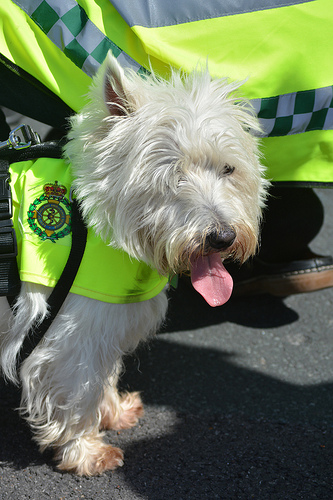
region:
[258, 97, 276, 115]
black square of fabric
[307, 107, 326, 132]
black square of fabric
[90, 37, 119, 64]
black square of fabric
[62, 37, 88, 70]
black square of fabric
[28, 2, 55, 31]
black square of fabric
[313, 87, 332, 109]
silver square of fabric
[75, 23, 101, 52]
silver square of fabric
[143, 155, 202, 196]
the eye of the dog is covered by hair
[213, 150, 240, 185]
the dog's eyes are black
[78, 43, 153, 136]
an ear is up on the dog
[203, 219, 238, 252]
the nose of the dog is black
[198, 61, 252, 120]
the dog's ear is buried in hair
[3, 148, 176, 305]
the dog is wearing a yellow coat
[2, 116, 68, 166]
the leash is attached to the dog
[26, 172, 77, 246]
an emblem is on the coat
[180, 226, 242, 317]
the doggie's tongue is pink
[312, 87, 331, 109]
grey colored fabric cloth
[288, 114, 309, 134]
grey colored fabric cloth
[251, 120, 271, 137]
grey colored fabric cloth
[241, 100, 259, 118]
grey colored fabric cloth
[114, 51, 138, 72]
grey colored fabric cloth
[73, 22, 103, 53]
grey colored fabric cloth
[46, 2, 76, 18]
grey colored fabric cloth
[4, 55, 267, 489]
This is a dog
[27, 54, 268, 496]
This is a dog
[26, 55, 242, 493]
This is a dog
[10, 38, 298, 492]
This is a dog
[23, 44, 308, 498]
This is a dog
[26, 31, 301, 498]
This is a dog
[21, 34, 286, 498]
This is a dog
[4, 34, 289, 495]
This is a dog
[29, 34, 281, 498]
This is a dog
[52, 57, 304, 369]
a shaggy dog face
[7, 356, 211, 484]
puppy feet on pavement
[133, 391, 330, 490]
shadow cast on concrete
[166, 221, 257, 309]
hot dog pants to beat the heat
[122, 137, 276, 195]
the dogs eyes are covered by fur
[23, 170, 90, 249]
a graphic on dog clothes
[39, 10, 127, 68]
a checkered part of banner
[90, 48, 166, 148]
pointed dog ears for exceptional hearing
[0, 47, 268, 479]
dog standing on concrete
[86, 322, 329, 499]
shadow of dog on ground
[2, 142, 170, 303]
dog wearing cloth on back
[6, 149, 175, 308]
dog's cloth is green